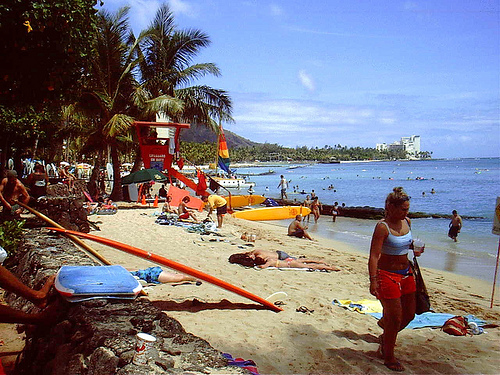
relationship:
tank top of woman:
[376, 215, 413, 256] [366, 190, 423, 370]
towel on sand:
[338, 284, 498, 352] [93, 211, 342, 367]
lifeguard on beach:
[96, 75, 230, 196] [114, 184, 423, 367]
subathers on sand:
[140, 175, 394, 295] [139, 212, 210, 259]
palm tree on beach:
[124, 0, 236, 177] [3, 162, 498, 372]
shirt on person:
[207, 194, 227, 209] [200, 194, 227, 227]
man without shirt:
[3, 170, 28, 215] [201, 195, 249, 209]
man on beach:
[288, 214, 314, 241] [141, 234, 341, 358]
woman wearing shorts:
[368, 186, 435, 371] [375, 267, 425, 302]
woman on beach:
[368, 186, 435, 371] [198, 230, 369, 323]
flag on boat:
[215, 125, 237, 178] [205, 175, 255, 187]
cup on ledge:
[408, 234, 438, 262] [112, 320, 167, 372]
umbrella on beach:
[119, 168, 168, 186] [3, 162, 498, 372]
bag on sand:
[441, 307, 482, 341] [129, 202, 322, 372]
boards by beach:
[231, 206, 313, 223] [91, 151, 499, 364]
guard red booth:
[147, 116, 167, 153] [114, 95, 246, 205]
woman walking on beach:
[366, 190, 423, 370] [256, 276, 364, 372]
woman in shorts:
[368, 186, 435, 371] [378, 270, 417, 298]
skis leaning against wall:
[11, 193, 298, 326] [14, 220, 239, 372]